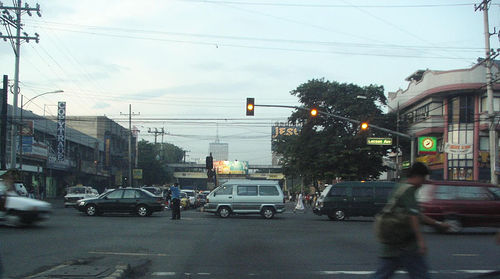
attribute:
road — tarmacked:
[5, 194, 482, 270]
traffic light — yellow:
[248, 95, 256, 115]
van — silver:
[206, 179, 286, 219]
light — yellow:
[243, 95, 256, 115]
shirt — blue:
[169, 186, 179, 201]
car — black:
[76, 190, 169, 216]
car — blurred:
[416, 181, 484, 231]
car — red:
[413, 180, 481, 232]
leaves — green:
[306, 84, 337, 109]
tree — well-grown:
[289, 70, 388, 199]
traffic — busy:
[4, 172, 461, 206]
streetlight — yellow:
[243, 92, 256, 120]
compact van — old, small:
[196, 180, 289, 215]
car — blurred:
[6, 186, 50, 228]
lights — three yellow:
[233, 94, 373, 153]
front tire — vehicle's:
[210, 205, 232, 215]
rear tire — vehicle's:
[258, 206, 278, 219]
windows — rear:
[235, 181, 282, 200]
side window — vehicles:
[232, 179, 254, 194]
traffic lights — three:
[232, 86, 414, 172]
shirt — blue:
[164, 184, 183, 197]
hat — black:
[396, 149, 431, 178]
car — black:
[71, 178, 169, 221]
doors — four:
[101, 200, 140, 211]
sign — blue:
[45, 89, 72, 170]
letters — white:
[59, 105, 64, 150]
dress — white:
[292, 197, 301, 217]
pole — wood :
[104, 81, 166, 233]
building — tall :
[79, 84, 177, 212]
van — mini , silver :
[195, 151, 342, 261]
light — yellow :
[290, 83, 341, 142]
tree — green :
[283, 59, 422, 254]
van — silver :
[181, 156, 305, 237]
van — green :
[216, 175, 286, 233]